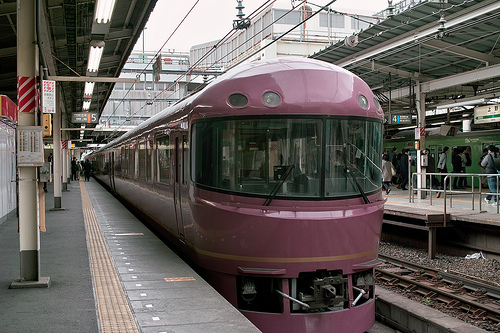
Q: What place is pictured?
A: It is a station.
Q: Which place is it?
A: It is a station.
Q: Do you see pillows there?
A: No, there are no pillows.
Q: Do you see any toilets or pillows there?
A: No, there are no pillows or toilets.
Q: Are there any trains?
A: Yes, there is a train.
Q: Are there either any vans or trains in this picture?
A: Yes, there is a train.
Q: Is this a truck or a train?
A: This is a train.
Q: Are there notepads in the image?
A: No, there are no notepads.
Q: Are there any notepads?
A: No, there are no notepads.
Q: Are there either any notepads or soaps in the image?
A: No, there are no notepads or soaps.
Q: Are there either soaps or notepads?
A: No, there are no notepads or soaps.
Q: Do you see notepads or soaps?
A: No, there are no notepads or soaps.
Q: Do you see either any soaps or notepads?
A: No, there are no notepads or soaps.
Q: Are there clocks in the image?
A: No, there are no clocks.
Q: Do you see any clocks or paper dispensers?
A: No, there are no clocks or paper dispensers.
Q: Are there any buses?
A: No, there are no buses.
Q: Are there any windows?
A: Yes, there is a window.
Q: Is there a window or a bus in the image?
A: Yes, there is a window.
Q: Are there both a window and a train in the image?
A: Yes, there are both a window and a train.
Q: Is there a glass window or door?
A: Yes, there is a glass window.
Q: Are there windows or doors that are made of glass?
A: Yes, the window is made of glass.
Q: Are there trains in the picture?
A: Yes, there is a train.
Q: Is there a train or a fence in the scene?
A: Yes, there is a train.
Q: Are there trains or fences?
A: Yes, there is a train.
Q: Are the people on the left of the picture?
A: Yes, the people are on the left of the image.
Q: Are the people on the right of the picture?
A: No, the people are on the left of the image.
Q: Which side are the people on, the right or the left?
A: The people are on the left of the image.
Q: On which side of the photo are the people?
A: The people are on the left of the image.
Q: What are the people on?
A: The people are on the platform.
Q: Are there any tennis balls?
A: No, there are no tennis balls.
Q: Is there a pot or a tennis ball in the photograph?
A: No, there are no tennis balls or pots.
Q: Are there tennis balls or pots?
A: No, there are no tennis balls or pots.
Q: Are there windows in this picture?
A: Yes, there is a window.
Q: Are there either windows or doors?
A: Yes, there is a window.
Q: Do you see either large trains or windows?
A: Yes, there is a large window.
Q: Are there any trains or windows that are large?
A: Yes, the window is large.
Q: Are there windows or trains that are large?
A: Yes, the window is large.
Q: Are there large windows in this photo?
A: Yes, there is a large window.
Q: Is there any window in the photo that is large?
A: Yes, there is a window that is large.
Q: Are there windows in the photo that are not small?
A: Yes, there is a large window.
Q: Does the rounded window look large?
A: Yes, the window is large.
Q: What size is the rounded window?
A: The window is large.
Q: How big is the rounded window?
A: The window is large.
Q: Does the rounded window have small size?
A: No, the window is large.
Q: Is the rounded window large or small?
A: The window is large.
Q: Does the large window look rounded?
A: Yes, the window is rounded.